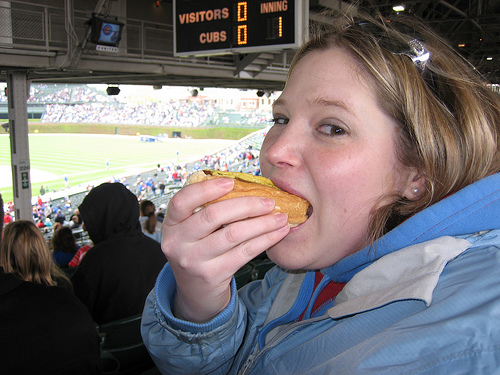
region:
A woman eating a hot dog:
[138, 27, 493, 371]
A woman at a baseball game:
[138, 25, 495, 370]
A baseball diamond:
[3, 125, 242, 207]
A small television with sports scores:
[88, 10, 126, 55]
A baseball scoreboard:
[171, 3, 311, 62]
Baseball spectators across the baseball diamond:
[3, 78, 273, 136]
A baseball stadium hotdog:
[183, 165, 313, 233]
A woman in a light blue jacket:
[138, 21, 498, 370]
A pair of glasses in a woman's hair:
[334, 13, 439, 93]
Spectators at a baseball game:
[4, 78, 287, 365]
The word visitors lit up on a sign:
[172, 4, 231, 27]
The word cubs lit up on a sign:
[195, 25, 231, 44]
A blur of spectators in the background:
[62, 100, 222, 129]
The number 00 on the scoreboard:
[234, 0, 251, 48]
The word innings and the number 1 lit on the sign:
[258, 0, 291, 45]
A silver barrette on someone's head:
[394, 28, 437, 80]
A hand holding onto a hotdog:
[162, 165, 318, 310]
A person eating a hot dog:
[155, 15, 385, 272]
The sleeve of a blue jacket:
[147, 266, 242, 356]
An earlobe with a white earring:
[400, 164, 430, 201]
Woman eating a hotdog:
[167, 47, 457, 276]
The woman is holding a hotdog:
[153, 151, 323, 314]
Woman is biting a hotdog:
[165, 158, 380, 283]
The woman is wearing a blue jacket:
[155, 220, 484, 373]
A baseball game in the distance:
[7, 109, 203, 212]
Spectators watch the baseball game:
[5, 160, 141, 360]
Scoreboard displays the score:
[176, 5, 307, 65]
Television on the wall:
[85, 13, 125, 58]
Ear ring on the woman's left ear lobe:
[397, 178, 427, 203]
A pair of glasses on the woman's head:
[337, 12, 440, 83]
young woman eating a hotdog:
[132, 16, 496, 373]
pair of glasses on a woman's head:
[333, 5, 433, 79]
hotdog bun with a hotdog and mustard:
[183, 158, 313, 228]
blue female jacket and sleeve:
[139, 267, 261, 368]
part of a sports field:
[32, 111, 249, 168]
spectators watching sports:
[37, 188, 131, 318]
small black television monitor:
[92, 17, 125, 57]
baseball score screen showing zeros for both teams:
[166, 3, 316, 60]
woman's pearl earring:
[380, 156, 435, 217]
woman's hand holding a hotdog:
[128, 170, 290, 292]